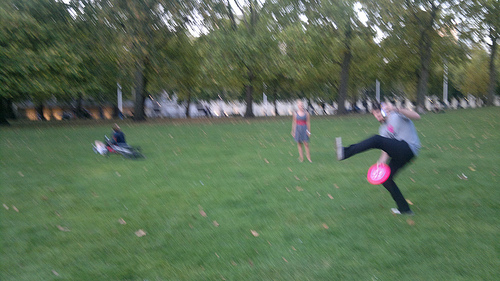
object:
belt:
[296, 120, 307, 126]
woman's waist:
[296, 123, 308, 137]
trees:
[0, 0, 499, 124]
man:
[335, 100, 424, 214]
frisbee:
[367, 162, 392, 184]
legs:
[335, 134, 416, 216]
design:
[386, 124, 398, 139]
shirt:
[376, 112, 421, 155]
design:
[372, 167, 384, 179]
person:
[291, 98, 313, 163]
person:
[90, 123, 147, 161]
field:
[1, 102, 497, 279]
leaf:
[118, 213, 131, 225]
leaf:
[132, 225, 147, 242]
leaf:
[195, 194, 209, 216]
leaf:
[233, 224, 266, 241]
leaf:
[312, 214, 329, 233]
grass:
[0, 111, 499, 280]